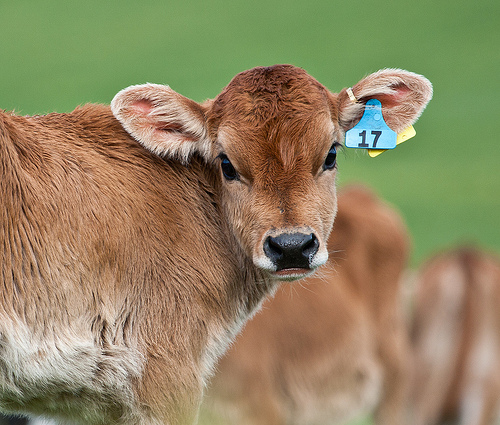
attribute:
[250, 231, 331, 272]
nose — black, small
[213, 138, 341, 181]
eyes — beady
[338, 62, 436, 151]
ear — fluffy